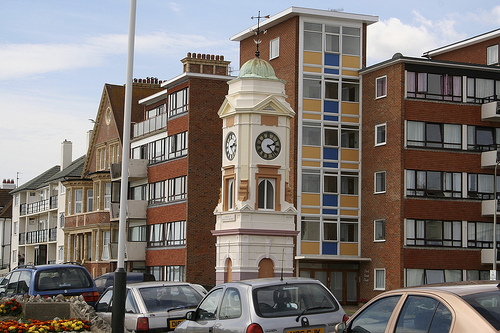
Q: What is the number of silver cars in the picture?
A: Two.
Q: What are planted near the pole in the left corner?
A: Flowers.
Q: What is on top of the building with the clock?
A: A weather vane.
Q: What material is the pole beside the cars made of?
A: Steel.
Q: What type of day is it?
A: A sunny day.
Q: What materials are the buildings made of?
A: Bricks.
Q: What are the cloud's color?
A: White.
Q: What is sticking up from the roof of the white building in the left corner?
A: A chimney.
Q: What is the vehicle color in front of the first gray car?
A: Blue.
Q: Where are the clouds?
A: In the sky.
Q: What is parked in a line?
A: Cars.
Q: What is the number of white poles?
A: One.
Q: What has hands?
A: Clocks.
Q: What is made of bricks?
A: Some of the buildings.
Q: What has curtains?
A: Building windows.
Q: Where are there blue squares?
A: Building wall right of clocks.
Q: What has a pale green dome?
A: Clock tower.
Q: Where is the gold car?
A: Bottom right.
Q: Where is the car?
A: Parked in a parking space.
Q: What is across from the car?
A: A building.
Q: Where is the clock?
A: At the top of the tower.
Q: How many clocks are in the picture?
A: Two.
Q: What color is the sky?
A: Blue.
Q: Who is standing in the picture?
A: No one.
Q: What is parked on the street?
A: Cars.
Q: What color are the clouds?
A: White.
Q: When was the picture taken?
A: During the day.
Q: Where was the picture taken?
A: On the street.